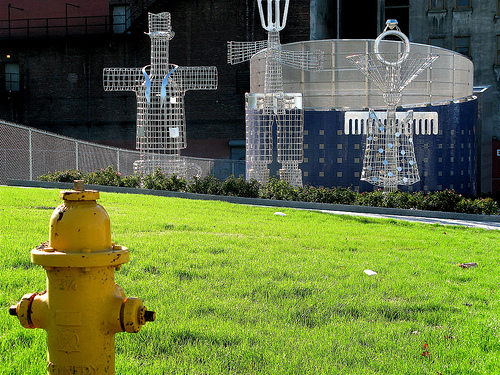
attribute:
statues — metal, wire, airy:
[106, 11, 416, 198]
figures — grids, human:
[103, 11, 437, 200]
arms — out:
[101, 65, 219, 92]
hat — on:
[144, 12, 176, 41]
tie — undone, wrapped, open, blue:
[142, 64, 180, 109]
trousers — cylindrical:
[245, 94, 302, 167]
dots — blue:
[366, 114, 418, 188]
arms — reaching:
[351, 56, 430, 104]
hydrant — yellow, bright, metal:
[12, 191, 155, 372]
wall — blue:
[227, 6, 498, 196]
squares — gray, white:
[302, 121, 482, 194]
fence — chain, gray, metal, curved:
[4, 116, 245, 189]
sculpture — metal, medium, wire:
[105, 11, 218, 179]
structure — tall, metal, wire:
[228, 3, 313, 187]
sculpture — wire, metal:
[346, 17, 440, 208]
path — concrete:
[78, 174, 499, 232]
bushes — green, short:
[50, 170, 498, 224]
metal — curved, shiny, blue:
[227, 69, 485, 196]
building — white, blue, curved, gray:
[233, 4, 496, 192]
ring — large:
[376, 20, 410, 68]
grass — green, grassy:
[2, 182, 500, 368]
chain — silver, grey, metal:
[2, 122, 246, 189]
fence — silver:
[1, 120, 247, 192]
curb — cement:
[7, 170, 500, 226]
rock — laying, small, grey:
[453, 262, 479, 271]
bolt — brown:
[145, 310, 157, 321]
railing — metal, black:
[2, 12, 189, 51]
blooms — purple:
[28, 169, 488, 220]